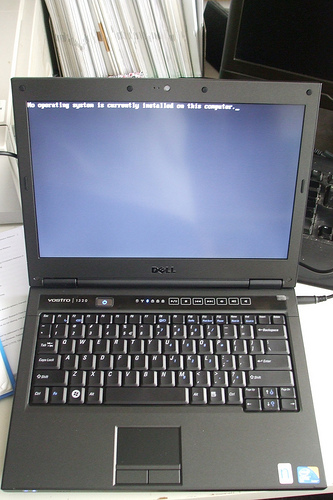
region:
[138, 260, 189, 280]
A black Dell laptop.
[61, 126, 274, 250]
The laptop has a blue screen.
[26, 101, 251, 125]
Windows needs to be installed.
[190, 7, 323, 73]
Black free standing monitor.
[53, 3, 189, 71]
White files in the background.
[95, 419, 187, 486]
A small black mouse pad.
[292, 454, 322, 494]
Small Windows symbol in the corner.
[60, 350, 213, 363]
Home row on the keyboard.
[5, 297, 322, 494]
Very small Dell laptop.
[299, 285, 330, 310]
Small piece of the power cord.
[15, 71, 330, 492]
photograph of a black lap top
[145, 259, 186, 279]
logo of lap top company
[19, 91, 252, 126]
blue screen with an error message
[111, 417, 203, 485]
lap tops mouse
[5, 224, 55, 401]
papers on table beside laptop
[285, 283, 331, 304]
black plug plugged into lap top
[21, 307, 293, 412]
black keyboard with white letters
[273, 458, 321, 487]
stickers on left corner of lap top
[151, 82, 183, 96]
camera window at top of lap top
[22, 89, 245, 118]
message states comptuer has no operating system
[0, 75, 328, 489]
A black Dell laptop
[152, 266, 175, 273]
The Dell logo on a laptop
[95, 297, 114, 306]
The power button on a laptop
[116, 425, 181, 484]
The mouse on a laptop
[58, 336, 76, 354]
The Q key on a laptop.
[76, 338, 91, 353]
The W key on a laptop.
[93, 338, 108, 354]
The E key on a laptop.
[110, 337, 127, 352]
The R key on a laptop.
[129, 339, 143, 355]
The T key on a laptop.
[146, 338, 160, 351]
The Y key on a laptop.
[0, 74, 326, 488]
an open laptop computer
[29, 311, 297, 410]
a black computer keyboard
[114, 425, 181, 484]
a computer track pad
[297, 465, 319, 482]
an Intel corporate sticker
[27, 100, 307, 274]
a computer display monitor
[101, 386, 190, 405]
a computer space bar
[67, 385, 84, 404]
a computer Windows key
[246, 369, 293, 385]
a computer shift key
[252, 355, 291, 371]
a computer return key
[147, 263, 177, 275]
DELL corporate printed logo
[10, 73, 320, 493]
black laptop computer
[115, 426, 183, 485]
mouse track pad on a laptop computer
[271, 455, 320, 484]
logo stickers on a black laptop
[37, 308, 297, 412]
black and white keys on a laptop keyboard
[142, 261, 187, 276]
Dell logo on a laptop computer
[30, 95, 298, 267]
blue screen on a laptop computer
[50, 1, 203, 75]
white paper booklets on a desk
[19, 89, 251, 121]
error message on a laptop computer screen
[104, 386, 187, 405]
spacebar on a laptop keyboard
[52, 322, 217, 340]
number keys on a laptop keyboard